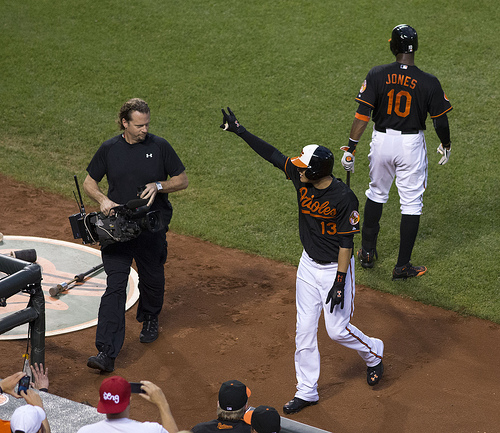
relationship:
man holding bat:
[340, 24, 454, 279] [337, 149, 367, 263]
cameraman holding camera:
[73, 94, 195, 374] [78, 199, 177, 254]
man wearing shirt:
[340, 21, 462, 274] [364, 56, 449, 130]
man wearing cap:
[340, 24, 454, 279] [381, 16, 420, 51]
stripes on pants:
[338, 260, 388, 365] [283, 252, 391, 404]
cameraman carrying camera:
[82, 98, 190, 373] [75, 207, 139, 249]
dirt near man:
[203, 289, 264, 336] [219, 107, 385, 415]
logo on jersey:
[288, 192, 350, 222] [251, 141, 376, 267]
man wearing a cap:
[75, 376, 178, 432] [97, 374, 132, 413]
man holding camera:
[75, 373, 178, 431] [130, 380, 141, 392]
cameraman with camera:
[82, 98, 190, 373] [67, 197, 160, 254]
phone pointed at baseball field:
[128, 382, 145, 394] [0, 0, 499, 325]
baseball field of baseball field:
[0, 0, 499, 325] [5, 3, 497, 328]